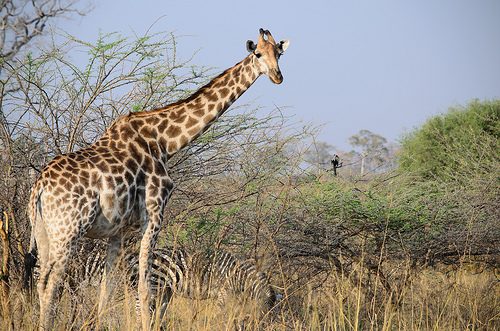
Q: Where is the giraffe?
A: In the brush.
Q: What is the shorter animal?
A: Zebra.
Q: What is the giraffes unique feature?
A: Long neck.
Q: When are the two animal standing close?
A: Daytime.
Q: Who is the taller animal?
A: Giraffe.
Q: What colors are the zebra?
A: Black and white.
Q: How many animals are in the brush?
A: Two.